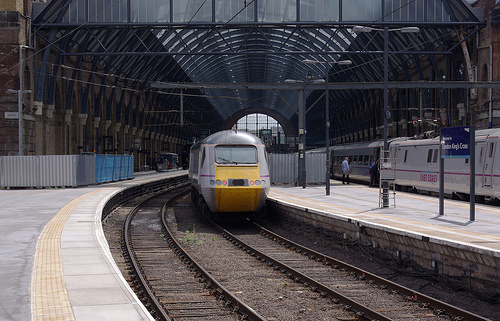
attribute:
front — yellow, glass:
[216, 162, 262, 205]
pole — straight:
[310, 49, 344, 204]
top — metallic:
[204, 110, 262, 152]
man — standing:
[330, 146, 360, 191]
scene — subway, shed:
[10, 24, 499, 270]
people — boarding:
[153, 135, 203, 187]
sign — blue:
[420, 125, 483, 160]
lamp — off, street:
[281, 34, 372, 86]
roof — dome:
[153, 13, 367, 126]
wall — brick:
[24, 138, 117, 194]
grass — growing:
[302, 175, 336, 187]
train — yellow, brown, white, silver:
[196, 117, 273, 205]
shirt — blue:
[336, 162, 355, 172]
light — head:
[236, 169, 267, 190]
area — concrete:
[2, 187, 105, 267]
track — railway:
[93, 202, 198, 271]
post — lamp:
[300, 64, 365, 208]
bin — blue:
[344, 153, 394, 187]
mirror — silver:
[259, 136, 276, 169]